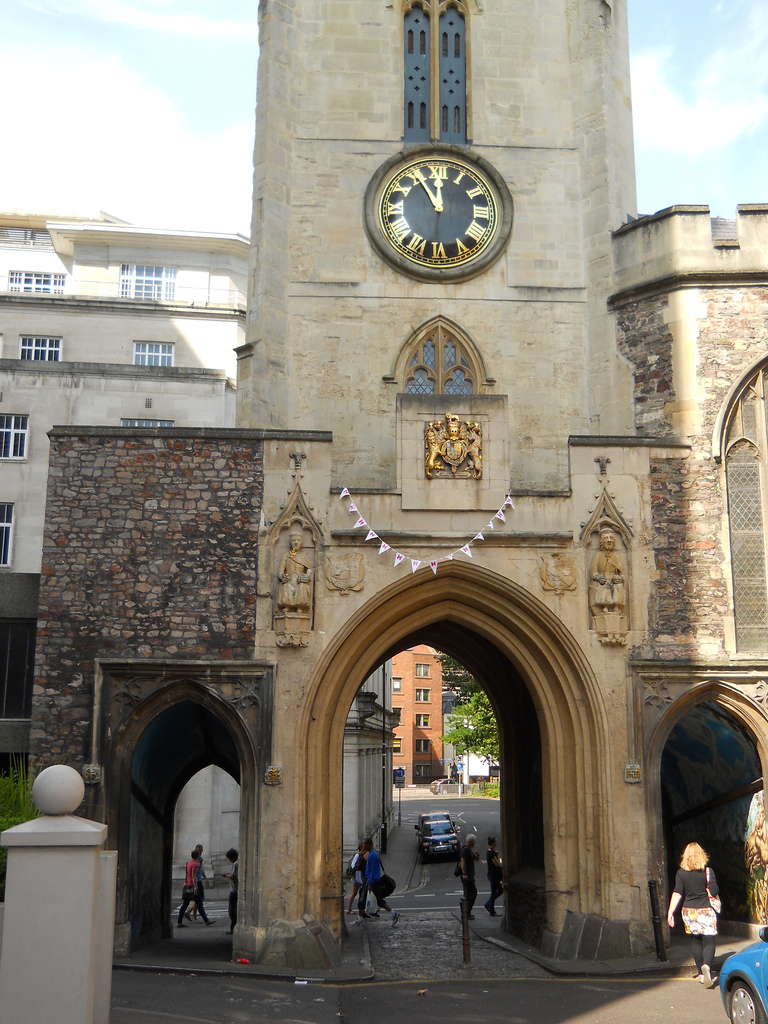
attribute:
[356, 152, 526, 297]
clock — large, round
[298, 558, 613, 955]
doorway — arched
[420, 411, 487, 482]
design — gold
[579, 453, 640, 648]
design — carved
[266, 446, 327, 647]
design — carved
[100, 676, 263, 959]
doorway — arched, small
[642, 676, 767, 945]
doorway — arched, small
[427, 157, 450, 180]
roman numeral — gold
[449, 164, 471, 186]
roman numeral — gold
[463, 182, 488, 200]
roman numeral — gold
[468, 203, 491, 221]
roman numeral — gold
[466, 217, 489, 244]
roman numeral — gold